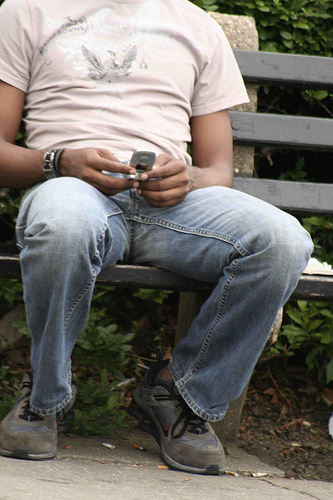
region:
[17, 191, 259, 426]
a person wearing blue color jean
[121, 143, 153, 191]
a person using mobile phone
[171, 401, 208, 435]
black color shoe lace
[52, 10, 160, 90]
some letters and pictures in the shirt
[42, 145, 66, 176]
wrist band in the person hand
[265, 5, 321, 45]
leaves of the plant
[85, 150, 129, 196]
finger of the person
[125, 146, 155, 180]
silver mobile in the person hand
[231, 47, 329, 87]
black wood on bench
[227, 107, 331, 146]
black wood on bench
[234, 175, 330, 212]
black wood on bench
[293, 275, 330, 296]
black wood on bench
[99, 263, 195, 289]
black wood on bench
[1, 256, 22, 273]
black wood on bench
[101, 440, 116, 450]
cigarette but on ground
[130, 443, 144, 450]
cigarette but on ground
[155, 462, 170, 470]
cigarette but on ground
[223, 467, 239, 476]
cigarette but on ground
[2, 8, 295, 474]
this is a man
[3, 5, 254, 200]
man wearing a pink shirt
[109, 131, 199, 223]
man holding a phone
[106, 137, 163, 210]
cell phone is a flip phone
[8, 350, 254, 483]
man wearing grey shoes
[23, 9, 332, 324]
man sitting on a bench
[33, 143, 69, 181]
man wearing a bracelet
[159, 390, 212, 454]
a black shoe string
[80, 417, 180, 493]
cigarette butt on the ground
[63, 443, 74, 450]
cigarette but on ground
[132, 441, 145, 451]
cigarette but on ground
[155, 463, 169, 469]
cigarette but on ground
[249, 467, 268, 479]
cigarette but on ground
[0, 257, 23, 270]
black board on bench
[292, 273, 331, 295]
black board on bench